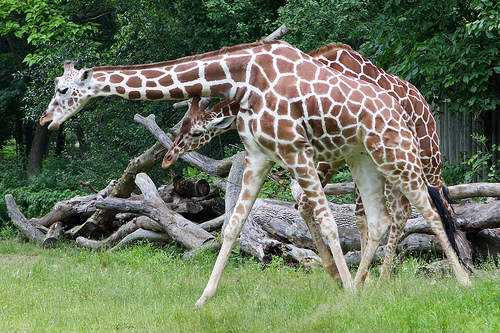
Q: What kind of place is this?
A: It is a field.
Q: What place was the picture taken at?
A: It was taken at the field.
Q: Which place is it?
A: It is a field.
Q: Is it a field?
A: Yes, it is a field.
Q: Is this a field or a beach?
A: It is a field.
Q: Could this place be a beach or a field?
A: It is a field.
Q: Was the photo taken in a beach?
A: No, the picture was taken in a field.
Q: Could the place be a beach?
A: No, it is a field.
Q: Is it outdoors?
A: Yes, it is outdoors.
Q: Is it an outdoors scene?
A: Yes, it is outdoors.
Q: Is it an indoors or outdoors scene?
A: It is outdoors.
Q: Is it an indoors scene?
A: No, it is outdoors.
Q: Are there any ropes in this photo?
A: No, there are no ropes.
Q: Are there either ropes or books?
A: No, there are no ropes or books.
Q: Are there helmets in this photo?
A: No, there are no helmets.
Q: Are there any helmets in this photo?
A: No, there are no helmets.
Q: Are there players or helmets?
A: No, there are no helmets or players.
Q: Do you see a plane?
A: No, there are no airplanes.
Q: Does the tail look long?
A: Yes, the tail is long.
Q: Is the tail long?
A: Yes, the tail is long.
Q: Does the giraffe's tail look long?
A: Yes, the tail is long.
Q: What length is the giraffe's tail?
A: The tail is long.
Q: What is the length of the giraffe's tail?
A: The tail is long.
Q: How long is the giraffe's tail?
A: The tail is long.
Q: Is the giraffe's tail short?
A: No, the tail is long.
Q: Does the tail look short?
A: No, the tail is long.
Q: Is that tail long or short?
A: The tail is long.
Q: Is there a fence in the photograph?
A: Yes, there is a fence.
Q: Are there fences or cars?
A: Yes, there is a fence.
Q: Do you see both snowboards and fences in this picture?
A: No, there is a fence but no snowboards.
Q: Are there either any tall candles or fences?
A: Yes, there is a tall fence.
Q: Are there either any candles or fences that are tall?
A: Yes, the fence is tall.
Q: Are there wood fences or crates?
A: Yes, there is a wood fence.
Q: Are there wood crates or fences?
A: Yes, there is a wood fence.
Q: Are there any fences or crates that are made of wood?
A: Yes, the fence is made of wood.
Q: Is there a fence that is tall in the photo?
A: Yes, there is a tall fence.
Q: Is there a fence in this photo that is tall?
A: Yes, there is a fence that is tall.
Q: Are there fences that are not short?
A: Yes, there is a tall fence.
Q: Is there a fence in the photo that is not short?
A: Yes, there is a tall fence.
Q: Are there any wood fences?
A: Yes, there is a wood fence.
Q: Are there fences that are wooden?
A: Yes, there is a fence that is wooden.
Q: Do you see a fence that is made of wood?
A: Yes, there is a fence that is made of wood.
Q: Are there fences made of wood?
A: Yes, there is a fence that is made of wood.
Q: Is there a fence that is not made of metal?
A: Yes, there is a fence that is made of wood.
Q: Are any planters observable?
A: No, there are no planters.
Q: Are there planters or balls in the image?
A: No, there are no planters or balls.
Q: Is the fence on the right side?
A: Yes, the fence is on the right of the image.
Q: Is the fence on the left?
A: No, the fence is on the right of the image.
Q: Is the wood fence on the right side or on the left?
A: The fence is on the right of the image.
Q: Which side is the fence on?
A: The fence is on the right of the image.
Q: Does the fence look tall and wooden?
A: Yes, the fence is tall and wooden.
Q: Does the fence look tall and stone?
A: No, the fence is tall but wooden.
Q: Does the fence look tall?
A: Yes, the fence is tall.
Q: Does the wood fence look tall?
A: Yes, the fence is tall.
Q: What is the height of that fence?
A: The fence is tall.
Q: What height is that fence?
A: The fence is tall.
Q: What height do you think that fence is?
A: The fence is tall.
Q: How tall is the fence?
A: The fence is tall.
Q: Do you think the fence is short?
A: No, the fence is tall.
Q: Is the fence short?
A: No, the fence is tall.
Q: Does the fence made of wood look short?
A: No, the fence is tall.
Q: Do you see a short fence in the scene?
A: No, there is a fence but it is tall.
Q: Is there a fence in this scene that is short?
A: No, there is a fence but it is tall.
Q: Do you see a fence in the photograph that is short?
A: No, there is a fence but it is tall.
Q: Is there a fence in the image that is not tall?
A: No, there is a fence but it is tall.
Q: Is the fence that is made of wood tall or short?
A: The fence is tall.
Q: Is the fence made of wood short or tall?
A: The fence is tall.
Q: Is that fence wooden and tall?
A: Yes, the fence is wooden and tall.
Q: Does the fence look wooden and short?
A: No, the fence is wooden but tall.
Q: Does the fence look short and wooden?
A: No, the fence is wooden but tall.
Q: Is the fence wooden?
A: Yes, the fence is wooden.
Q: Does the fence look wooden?
A: Yes, the fence is wooden.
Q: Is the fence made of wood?
A: Yes, the fence is made of wood.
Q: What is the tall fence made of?
A: The fence is made of wood.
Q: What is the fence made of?
A: The fence is made of wood.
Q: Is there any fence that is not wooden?
A: No, there is a fence but it is wooden.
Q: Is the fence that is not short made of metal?
A: No, the fence is made of wood.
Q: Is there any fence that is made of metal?
A: No, there is a fence but it is made of wood.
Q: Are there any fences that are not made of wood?
A: No, there is a fence but it is made of wood.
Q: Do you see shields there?
A: No, there are no shields.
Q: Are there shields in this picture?
A: No, there are no shields.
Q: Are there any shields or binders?
A: No, there are no shields or binders.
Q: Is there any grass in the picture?
A: Yes, there is grass.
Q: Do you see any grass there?
A: Yes, there is grass.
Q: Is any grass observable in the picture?
A: Yes, there is grass.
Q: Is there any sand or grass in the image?
A: Yes, there is grass.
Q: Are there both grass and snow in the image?
A: No, there is grass but no snow.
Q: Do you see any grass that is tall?
A: Yes, there is tall grass.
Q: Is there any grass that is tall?
A: Yes, there is grass that is tall.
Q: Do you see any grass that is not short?
A: Yes, there is tall grass.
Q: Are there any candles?
A: No, there are no candles.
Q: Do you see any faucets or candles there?
A: No, there are no candles or faucets.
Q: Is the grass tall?
A: Yes, the grass is tall.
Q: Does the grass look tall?
A: Yes, the grass is tall.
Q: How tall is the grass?
A: The grass is tall.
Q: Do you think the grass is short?
A: No, the grass is tall.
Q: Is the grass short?
A: No, the grass is tall.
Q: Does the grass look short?
A: No, the grass is tall.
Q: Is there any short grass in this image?
A: No, there is grass but it is tall.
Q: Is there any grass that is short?
A: No, there is grass but it is tall.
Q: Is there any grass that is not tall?
A: No, there is grass but it is tall.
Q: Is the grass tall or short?
A: The grass is tall.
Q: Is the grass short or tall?
A: The grass is tall.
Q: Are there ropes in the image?
A: No, there are no ropes.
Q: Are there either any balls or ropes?
A: No, there are no ropes or balls.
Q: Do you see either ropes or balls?
A: No, there are no ropes or balls.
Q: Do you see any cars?
A: No, there are no cars.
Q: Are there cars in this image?
A: No, there are no cars.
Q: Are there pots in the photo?
A: No, there are no pots.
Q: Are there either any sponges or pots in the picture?
A: No, there are no pots or sponges.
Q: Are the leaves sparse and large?
A: No, the leaves are large but dense.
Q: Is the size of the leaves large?
A: Yes, the leaves are large.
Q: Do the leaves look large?
A: Yes, the leaves are large.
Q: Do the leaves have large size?
A: Yes, the leaves are large.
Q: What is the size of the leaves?
A: The leaves are large.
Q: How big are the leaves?
A: The leaves are large.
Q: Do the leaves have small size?
A: No, the leaves are large.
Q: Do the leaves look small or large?
A: The leaves are large.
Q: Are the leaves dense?
A: Yes, the leaves are dense.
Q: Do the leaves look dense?
A: Yes, the leaves are dense.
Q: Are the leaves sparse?
A: No, the leaves are dense.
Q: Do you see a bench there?
A: No, there are no benches.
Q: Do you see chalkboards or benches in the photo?
A: No, there are no benches or chalkboards.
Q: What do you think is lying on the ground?
A: The logs are lying on the ground.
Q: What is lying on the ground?
A: The logs are lying on the ground.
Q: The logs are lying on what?
A: The logs are lying on the ground.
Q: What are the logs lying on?
A: The logs are lying on the ground.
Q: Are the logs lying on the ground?
A: Yes, the logs are lying on the ground.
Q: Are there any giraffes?
A: Yes, there is a giraffe.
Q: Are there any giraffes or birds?
A: Yes, there is a giraffe.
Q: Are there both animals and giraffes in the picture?
A: Yes, there are both a giraffe and animals.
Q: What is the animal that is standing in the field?
A: The animal is a giraffe.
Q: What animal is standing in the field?
A: The animal is a giraffe.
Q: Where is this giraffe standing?
A: The giraffe is standing in the field.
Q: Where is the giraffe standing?
A: The giraffe is standing in the field.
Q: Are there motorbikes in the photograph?
A: No, there are no motorbikes.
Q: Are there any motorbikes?
A: No, there are no motorbikes.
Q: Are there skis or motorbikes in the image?
A: No, there are no motorbikes or skis.